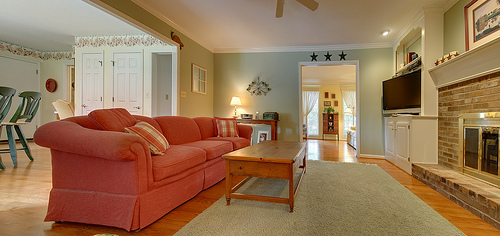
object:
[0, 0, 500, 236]
living room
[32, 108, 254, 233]
sofa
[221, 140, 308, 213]
table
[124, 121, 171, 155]
pillow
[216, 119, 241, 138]
pillow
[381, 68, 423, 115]
television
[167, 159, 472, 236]
rug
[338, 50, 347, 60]
star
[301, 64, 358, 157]
door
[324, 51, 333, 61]
star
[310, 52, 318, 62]
star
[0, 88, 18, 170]
chair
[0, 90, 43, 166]
chair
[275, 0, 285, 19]
blade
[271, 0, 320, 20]
fan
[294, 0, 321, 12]
blade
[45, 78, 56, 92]
plate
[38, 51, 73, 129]
wall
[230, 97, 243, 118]
lamp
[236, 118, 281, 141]
table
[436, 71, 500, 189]
fireplace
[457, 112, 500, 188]
door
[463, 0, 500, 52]
picture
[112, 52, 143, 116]
door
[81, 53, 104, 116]
door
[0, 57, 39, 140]
door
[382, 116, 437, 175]
cabinet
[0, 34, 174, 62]
wallpaper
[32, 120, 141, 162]
arm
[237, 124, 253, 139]
arm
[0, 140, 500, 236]
floor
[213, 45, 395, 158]
wall